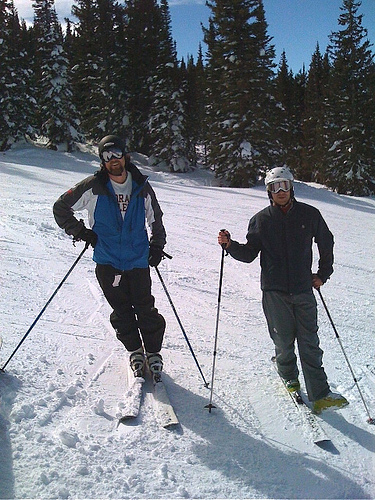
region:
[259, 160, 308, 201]
the helmet is white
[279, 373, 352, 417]
the skateboots are yellow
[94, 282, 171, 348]
the pants are black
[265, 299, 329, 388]
the pants are grey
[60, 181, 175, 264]
the jacket is blue ,black and white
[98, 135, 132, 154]
the helmet is black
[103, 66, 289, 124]
there is snow on the tress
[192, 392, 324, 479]
there is shadow on the ground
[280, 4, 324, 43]
the sky is blue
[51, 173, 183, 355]
his hand is on his side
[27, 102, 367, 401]
People who are skiing.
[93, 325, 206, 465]
Skis under the man.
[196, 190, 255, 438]
Man holding a pole.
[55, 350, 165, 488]
Snow on the ground.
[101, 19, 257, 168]
Trees in the background.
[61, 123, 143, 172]
Goggles on the man.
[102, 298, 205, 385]
Boots on the man.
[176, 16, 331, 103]
Sky behind the trees.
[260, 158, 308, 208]
White helmet on the man.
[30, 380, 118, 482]
Chunks of snow on the ground.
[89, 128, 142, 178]
a man with facial hair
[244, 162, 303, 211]
a man wearing a white helmet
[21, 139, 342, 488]
two men wearing skis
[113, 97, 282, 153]
snowed covered trees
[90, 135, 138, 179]
a man wearing goggles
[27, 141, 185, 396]
a man holding ski poles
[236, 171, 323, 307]
a man wearing a black jacket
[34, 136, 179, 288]
a man wearing a black, blue and white jacket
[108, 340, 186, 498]
a set of skis covered in snow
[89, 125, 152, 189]
a man smiling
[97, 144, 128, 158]
snow goggle covering eyes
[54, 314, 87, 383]
tracks in the snow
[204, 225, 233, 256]
a hand grasping ski pole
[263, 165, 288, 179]
a gray helmet on a head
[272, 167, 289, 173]
ventilation holes in the helmet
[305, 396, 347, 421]
yellow snow boot covered in snow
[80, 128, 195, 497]
a man wearing a blue and black jacket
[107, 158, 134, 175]
a beard around a mouth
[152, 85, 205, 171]
green pine trees covered in snow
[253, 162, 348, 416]
a man wearing gray pants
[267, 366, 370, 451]
pair of yellow ski boots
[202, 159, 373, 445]
male skiier with black jacket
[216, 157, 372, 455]
male skiier with white helmet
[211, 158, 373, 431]
male skiier with gray pants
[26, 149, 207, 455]
adult male skiier with blue and white jacket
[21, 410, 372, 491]
trampled snow at ski resort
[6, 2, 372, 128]
evergreen trees in distance with snow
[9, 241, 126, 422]
ski pole stuck in snow at an angle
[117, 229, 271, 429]
two ski poles almost touching each other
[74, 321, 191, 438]
skiis with snow over them